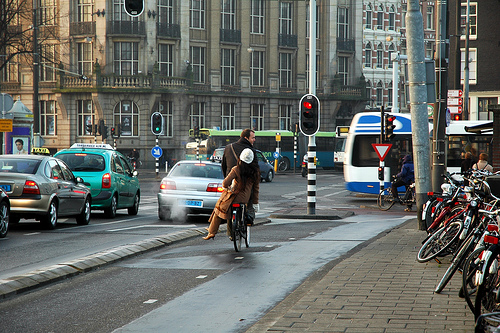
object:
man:
[220, 127, 260, 224]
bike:
[228, 197, 255, 251]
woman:
[202, 146, 259, 240]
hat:
[238, 147, 256, 165]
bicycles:
[473, 221, 500, 333]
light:
[301, 98, 313, 113]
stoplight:
[299, 92, 321, 139]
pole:
[306, 0, 318, 217]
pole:
[293, 133, 299, 172]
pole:
[154, 137, 163, 175]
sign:
[371, 142, 394, 163]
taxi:
[50, 142, 142, 218]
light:
[155, 126, 161, 133]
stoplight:
[149, 111, 164, 137]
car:
[157, 158, 226, 222]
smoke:
[167, 197, 191, 223]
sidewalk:
[247, 215, 495, 332]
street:
[1, 169, 411, 331]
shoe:
[202, 232, 217, 242]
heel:
[210, 235, 215, 241]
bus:
[342, 110, 498, 201]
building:
[1, 1, 369, 168]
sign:
[150, 145, 164, 160]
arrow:
[153, 147, 161, 159]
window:
[190, 47, 201, 66]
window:
[223, 65, 231, 84]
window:
[251, 52, 259, 68]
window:
[280, 69, 288, 88]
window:
[159, 44, 171, 63]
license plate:
[184, 199, 204, 206]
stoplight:
[290, 122, 300, 137]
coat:
[206, 165, 261, 221]